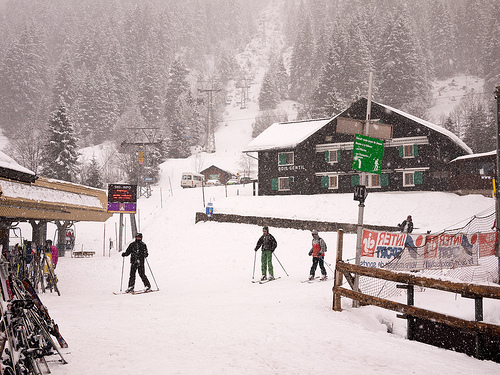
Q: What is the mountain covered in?
A: Snow.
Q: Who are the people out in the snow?
A: Skiers.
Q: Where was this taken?
A: At a ski resort.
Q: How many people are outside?
A: Five.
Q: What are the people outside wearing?
A: Cold weather clothing.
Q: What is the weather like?
A: It is snowing.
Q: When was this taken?
A: During the day.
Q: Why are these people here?
A: They are skiing.